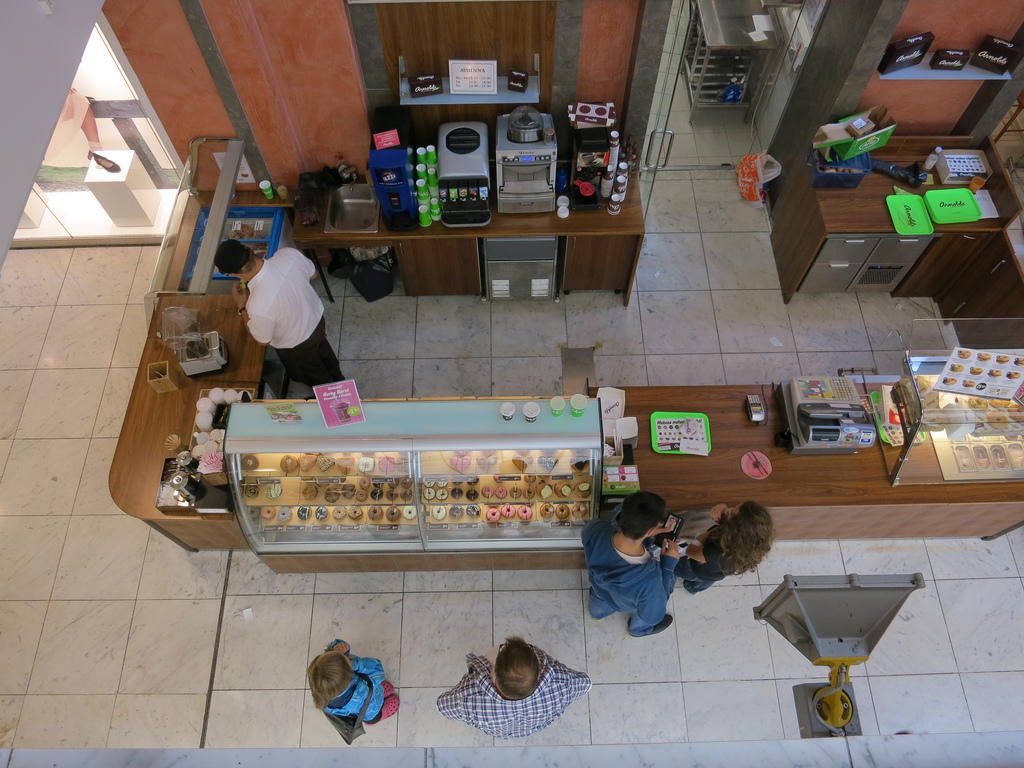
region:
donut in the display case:
[291, 498, 307, 519]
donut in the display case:
[329, 501, 340, 515]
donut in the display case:
[343, 501, 359, 520]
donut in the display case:
[381, 501, 400, 522]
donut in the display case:
[424, 498, 450, 522]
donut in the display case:
[460, 501, 479, 517]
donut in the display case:
[482, 501, 498, 521]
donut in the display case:
[497, 501, 511, 515]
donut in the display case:
[514, 500, 533, 521]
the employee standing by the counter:
[214, 233, 351, 395]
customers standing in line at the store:
[302, 499, 777, 740]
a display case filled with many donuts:
[227, 401, 602, 547]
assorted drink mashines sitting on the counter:
[436, 114, 623, 226]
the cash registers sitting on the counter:
[786, 379, 873, 447]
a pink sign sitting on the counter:
[315, 379, 373, 431]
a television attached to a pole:
[749, 563, 920, 735]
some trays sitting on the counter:
[876, 181, 976, 238]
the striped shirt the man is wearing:
[426, 653, 594, 734]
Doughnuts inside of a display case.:
[238, 458, 587, 531]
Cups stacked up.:
[598, 105, 633, 216]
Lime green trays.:
[887, 173, 976, 243]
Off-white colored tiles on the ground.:
[2, 168, 1012, 766]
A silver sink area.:
[313, 165, 380, 239]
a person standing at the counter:
[593, 502, 666, 616]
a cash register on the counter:
[783, 366, 869, 444]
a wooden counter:
[142, 170, 238, 525]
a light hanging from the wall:
[767, 563, 944, 709]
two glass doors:
[588, 66, 794, 243]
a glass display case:
[226, 402, 604, 551]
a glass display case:
[869, 356, 1022, 489]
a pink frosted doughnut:
[482, 506, 503, 523]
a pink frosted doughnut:
[499, 503, 516, 522]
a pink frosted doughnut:
[514, 506, 533, 523]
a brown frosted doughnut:
[539, 501, 553, 518]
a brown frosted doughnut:
[556, 503, 570, 522]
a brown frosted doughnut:
[568, 501, 587, 518]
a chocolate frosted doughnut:
[297, 503, 311, 520]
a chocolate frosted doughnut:
[313, 506, 330, 520]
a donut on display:
[545, 509, 566, 542]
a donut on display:
[507, 509, 526, 522]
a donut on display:
[419, 493, 449, 516]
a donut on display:
[374, 461, 406, 504]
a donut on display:
[353, 490, 380, 514]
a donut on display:
[346, 500, 360, 521]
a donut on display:
[336, 502, 343, 513]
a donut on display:
[292, 499, 318, 522]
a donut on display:
[485, 443, 515, 482]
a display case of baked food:
[203, 386, 606, 571]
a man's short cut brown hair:
[494, 635, 543, 702]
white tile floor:
[0, 230, 228, 755]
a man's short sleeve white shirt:
[232, 243, 324, 348]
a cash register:
[779, 367, 884, 457]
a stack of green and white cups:
[416, 200, 433, 227]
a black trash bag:
[314, 249, 394, 285]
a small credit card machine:
[740, 388, 769, 433]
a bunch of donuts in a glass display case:
[240, 503, 297, 527]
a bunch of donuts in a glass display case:
[290, 505, 347, 526]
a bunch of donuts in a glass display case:
[345, 499, 419, 526]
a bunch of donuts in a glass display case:
[237, 478, 295, 498]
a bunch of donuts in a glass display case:
[353, 481, 415, 505]